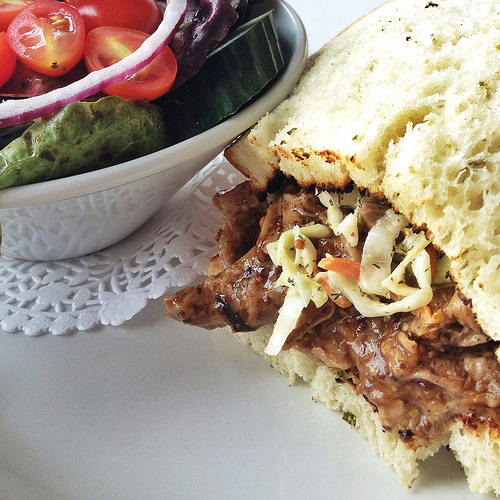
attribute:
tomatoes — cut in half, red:
[2, 1, 177, 104]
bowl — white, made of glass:
[2, 3, 310, 259]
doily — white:
[1, 157, 247, 341]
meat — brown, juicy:
[163, 167, 499, 452]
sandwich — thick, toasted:
[163, 3, 498, 498]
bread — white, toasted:
[219, 4, 498, 371]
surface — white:
[3, 1, 500, 500]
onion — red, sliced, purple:
[2, 1, 192, 129]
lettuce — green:
[2, 93, 169, 194]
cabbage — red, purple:
[170, 2, 239, 88]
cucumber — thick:
[160, 9, 286, 140]